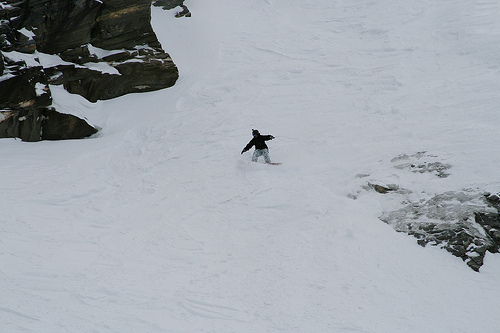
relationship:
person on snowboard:
[230, 125, 276, 166] [248, 147, 283, 164]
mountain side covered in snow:
[5, 7, 497, 332] [143, 12, 374, 332]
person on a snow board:
[229, 115, 292, 175] [243, 150, 310, 181]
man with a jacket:
[238, 126, 279, 168] [240, 135, 270, 150]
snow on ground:
[286, 58, 456, 154] [218, 19, 495, 146]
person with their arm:
[240, 127, 275, 162] [241, 140, 252, 155]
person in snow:
[242, 126, 282, 163] [0, 3, 498, 330]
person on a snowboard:
[241, 127, 273, 164] [263, 160, 280, 166]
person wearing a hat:
[225, 124, 287, 171] [240, 121, 268, 138]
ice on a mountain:
[388, 174, 499, 266] [363, 151, 495, 286]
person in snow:
[243, 127, 274, 165] [0, 3, 498, 330]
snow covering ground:
[206, 214, 381, 328] [187, 204, 441, 318]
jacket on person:
[236, 125, 291, 154] [206, 99, 303, 172]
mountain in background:
[0, 2, 497, 330] [8, 7, 430, 250]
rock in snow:
[356, 161, 490, 291] [75, 153, 251, 311]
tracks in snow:
[2, 253, 225, 325] [3, 242, 248, 330]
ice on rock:
[356, 151, 498, 271] [1, 0, 497, 330]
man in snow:
[218, 107, 285, 179] [210, 197, 380, 316]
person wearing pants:
[237, 125, 277, 165] [248, 147, 274, 163]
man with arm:
[238, 126, 279, 168] [262, 133, 277, 142]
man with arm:
[238, 126, 279, 168] [237, 135, 257, 154]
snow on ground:
[0, 3, 498, 330] [269, 40, 498, 124]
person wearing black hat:
[197, 101, 325, 197] [241, 125, 265, 141]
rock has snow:
[0, 0, 192, 142] [159, 27, 388, 133]